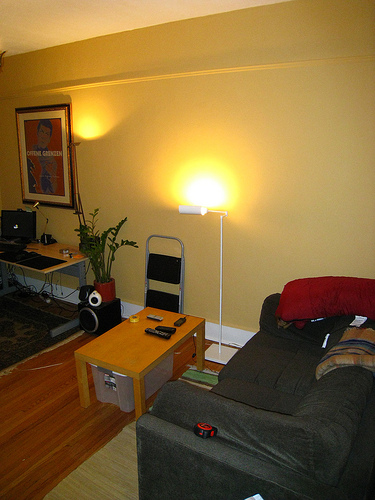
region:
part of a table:
[128, 360, 134, 366]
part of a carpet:
[90, 473, 102, 486]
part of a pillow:
[274, 386, 277, 399]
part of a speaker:
[105, 318, 111, 326]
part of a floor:
[123, 467, 133, 476]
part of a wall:
[226, 306, 234, 324]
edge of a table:
[134, 359, 139, 365]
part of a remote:
[149, 326, 156, 330]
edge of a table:
[131, 333, 140, 341]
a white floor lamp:
[172, 203, 242, 368]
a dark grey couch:
[138, 291, 371, 497]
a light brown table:
[73, 306, 206, 417]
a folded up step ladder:
[141, 233, 184, 312]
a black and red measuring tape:
[192, 420, 217, 438]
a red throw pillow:
[274, 273, 372, 319]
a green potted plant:
[73, 210, 137, 302]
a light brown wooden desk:
[1, 236, 94, 337]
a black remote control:
[143, 325, 171, 339]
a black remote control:
[154, 324, 175, 333]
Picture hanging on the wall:
[12, 100, 81, 211]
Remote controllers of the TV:
[141, 321, 178, 341]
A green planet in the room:
[68, 206, 141, 305]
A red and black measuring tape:
[191, 419, 219, 438]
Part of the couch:
[259, 351, 292, 401]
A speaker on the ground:
[74, 296, 123, 338]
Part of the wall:
[251, 84, 293, 159]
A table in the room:
[72, 304, 209, 419]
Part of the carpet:
[7, 310, 28, 351]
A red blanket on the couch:
[270, 272, 371, 329]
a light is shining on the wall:
[155, 141, 263, 218]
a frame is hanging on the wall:
[14, 100, 78, 208]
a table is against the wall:
[4, 226, 92, 350]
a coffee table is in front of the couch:
[73, 305, 204, 419]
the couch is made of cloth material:
[134, 290, 374, 498]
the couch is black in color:
[155, 287, 371, 495]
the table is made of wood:
[77, 302, 205, 417]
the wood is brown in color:
[76, 304, 204, 414]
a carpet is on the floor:
[2, 278, 94, 384]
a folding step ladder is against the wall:
[142, 233, 185, 318]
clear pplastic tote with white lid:
[89, 352, 176, 410]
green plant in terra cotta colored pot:
[75, 204, 140, 299]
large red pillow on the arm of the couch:
[274, 274, 374, 319]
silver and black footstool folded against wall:
[143, 233, 184, 311]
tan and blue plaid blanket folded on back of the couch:
[314, 324, 374, 377]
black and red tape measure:
[193, 423, 217, 439]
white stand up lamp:
[175, 204, 237, 368]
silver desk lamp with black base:
[32, 198, 56, 248]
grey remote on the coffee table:
[145, 312, 163, 321]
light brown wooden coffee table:
[74, 306, 205, 419]